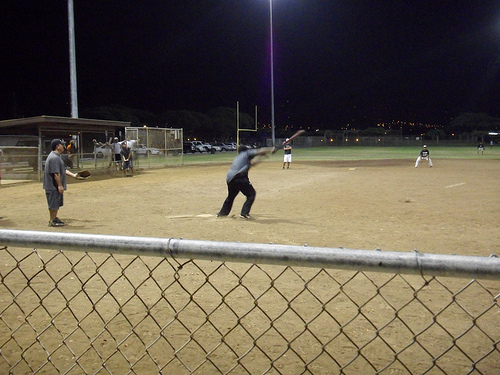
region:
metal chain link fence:
[0, 224, 499, 373]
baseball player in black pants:
[214, 127, 310, 222]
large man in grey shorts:
[34, 134, 96, 229]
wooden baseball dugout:
[0, 113, 140, 173]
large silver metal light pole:
[59, 0, 84, 117]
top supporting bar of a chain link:
[1, 221, 498, 295]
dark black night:
[4, 1, 499, 151]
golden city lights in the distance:
[199, 99, 479, 144]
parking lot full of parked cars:
[178, 133, 264, 157]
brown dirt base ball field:
[8, 154, 498, 371]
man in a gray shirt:
[35, 137, 76, 228]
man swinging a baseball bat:
[202, 123, 300, 221]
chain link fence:
[16, 230, 464, 372]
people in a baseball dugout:
[73, 113, 190, 178]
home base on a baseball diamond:
[164, 203, 213, 228]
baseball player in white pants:
[408, 127, 442, 184]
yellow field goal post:
[216, 91, 259, 151]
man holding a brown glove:
[36, 133, 96, 226]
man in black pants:
[202, 144, 302, 220]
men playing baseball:
[24, 113, 449, 220]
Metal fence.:
[274, 249, 447, 277]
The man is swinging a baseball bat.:
[226, 140, 286, 215]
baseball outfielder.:
[412, 139, 448, 173]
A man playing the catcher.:
[43, 140, 93, 221]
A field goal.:
[227, 100, 269, 144]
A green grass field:
[322, 143, 381, 156]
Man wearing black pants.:
[232, 174, 270, 218]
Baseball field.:
[317, 188, 444, 233]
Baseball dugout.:
[17, 126, 125, 138]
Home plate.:
[186, 208, 220, 228]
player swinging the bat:
[214, 130, 320, 230]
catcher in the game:
[20, 131, 105, 216]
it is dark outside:
[168, 25, 479, 127]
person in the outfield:
[461, 134, 491, 167]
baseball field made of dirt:
[320, 171, 455, 263]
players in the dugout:
[6, 112, 162, 184]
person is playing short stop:
[401, 139, 456, 190]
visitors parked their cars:
[188, 128, 253, 159]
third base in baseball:
[341, 160, 378, 181]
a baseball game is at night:
[8, 5, 498, 369]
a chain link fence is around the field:
[1, 226, 498, 371]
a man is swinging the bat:
[218, 125, 305, 220]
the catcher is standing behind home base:
[39, 136, 93, 228]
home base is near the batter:
[188, 204, 221, 227]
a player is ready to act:
[407, 135, 452, 171]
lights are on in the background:
[220, 115, 480, 155]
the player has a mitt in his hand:
[40, 136, 95, 188]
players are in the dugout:
[3, 109, 138, 210]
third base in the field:
[338, 160, 363, 180]